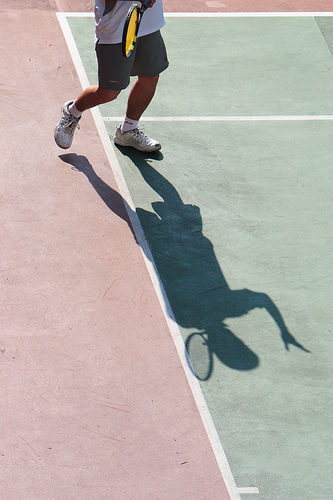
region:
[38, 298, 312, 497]
Red and green court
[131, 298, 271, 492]
The court has white lines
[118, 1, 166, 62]
Black and yellow tennis racket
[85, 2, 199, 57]
The person has a white shirt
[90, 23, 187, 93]
The person has grey shorts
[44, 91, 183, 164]
The person is wearing white shoes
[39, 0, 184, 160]
The person is walking across the court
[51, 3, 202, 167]
The person is holding a tennis racket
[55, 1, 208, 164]
The person is standing on the green side of the court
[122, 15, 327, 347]
The court has a green square in the center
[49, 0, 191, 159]
person playing tennis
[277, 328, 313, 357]
shadow of their hand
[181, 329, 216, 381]
shadow of the tennis racquet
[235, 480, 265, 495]
short white line on the tennis court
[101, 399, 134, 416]
scuff mark on the tennis court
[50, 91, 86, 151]
foot lifted a little off the ground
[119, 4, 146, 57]
black and yellow racquet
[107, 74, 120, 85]
tiny logo on the shorts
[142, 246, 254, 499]
long, thick, white line painted on the ground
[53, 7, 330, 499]
tennis court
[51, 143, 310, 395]
shadow of a tennis player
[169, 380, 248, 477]
white line on court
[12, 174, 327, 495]
green and red tennis court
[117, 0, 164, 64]
tennis racket with yellow strings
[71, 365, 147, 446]
scuff marks on court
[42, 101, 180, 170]
pair of white tennis shoes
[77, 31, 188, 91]
grey pair of shorts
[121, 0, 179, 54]
a black tennis racket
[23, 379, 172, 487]
some red painted ground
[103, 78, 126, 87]
a white and red logo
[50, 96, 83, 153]
the tennis player is wearing white sneakers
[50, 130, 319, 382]
the sun has cast the shadow of the tennis player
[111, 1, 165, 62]
the tennis racket is has yellow netting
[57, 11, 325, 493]
the tennis court is green with white lines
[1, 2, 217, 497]
the court is made of red clay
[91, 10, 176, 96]
the tennis players shorts are green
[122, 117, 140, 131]
the socks have red and blue writing on the side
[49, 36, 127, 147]
the players foot on this leg is in midair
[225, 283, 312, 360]
one of the arms is raised in the air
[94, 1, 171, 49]
the tee shirt is gray and green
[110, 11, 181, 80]
Person holding racket in hand.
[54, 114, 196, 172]
Person wearing white shoes.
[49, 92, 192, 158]
Person wearing white socks.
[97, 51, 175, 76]
Person wearing gray shorts.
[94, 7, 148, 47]
Person wearing white shirt.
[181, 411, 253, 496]
White line on tennis court.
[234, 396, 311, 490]
Tennis court is grayish in color.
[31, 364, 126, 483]
Reddish area on court.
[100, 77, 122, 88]
Red and white markings on shorts.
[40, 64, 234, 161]
Person is standing on tennis court.